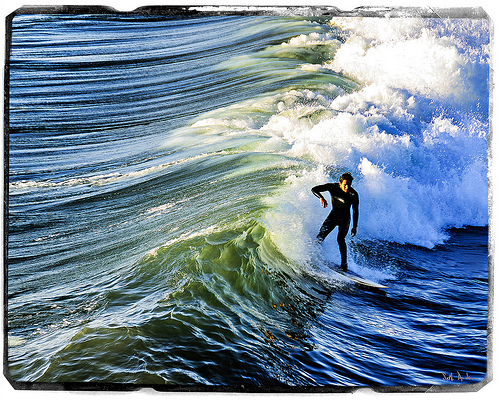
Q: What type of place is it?
A: It is an ocean.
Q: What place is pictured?
A: It is an ocean.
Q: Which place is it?
A: It is an ocean.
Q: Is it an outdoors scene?
A: Yes, it is outdoors.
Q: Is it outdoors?
A: Yes, it is outdoors.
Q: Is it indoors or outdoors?
A: It is outdoors.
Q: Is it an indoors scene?
A: No, it is outdoors.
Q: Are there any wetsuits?
A: Yes, there is a wetsuit.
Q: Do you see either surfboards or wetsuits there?
A: Yes, there is a wetsuit.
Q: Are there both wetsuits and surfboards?
A: Yes, there are both a wetsuit and a surfboard.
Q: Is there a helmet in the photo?
A: No, there are no helmets.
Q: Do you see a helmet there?
A: No, there are no helmets.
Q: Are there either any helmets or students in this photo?
A: No, there are no helmets or students.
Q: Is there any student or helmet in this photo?
A: No, there are no helmets or students.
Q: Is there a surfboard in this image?
A: Yes, there is a surfboard.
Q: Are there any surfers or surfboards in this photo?
A: Yes, there is a surfboard.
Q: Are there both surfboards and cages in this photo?
A: No, there is a surfboard but no cages.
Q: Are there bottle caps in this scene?
A: No, there are no bottle caps.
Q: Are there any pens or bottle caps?
A: No, there are no bottle caps or pens.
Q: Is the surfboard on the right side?
A: Yes, the surfboard is on the right of the image.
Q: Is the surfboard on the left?
A: No, the surfboard is on the right of the image.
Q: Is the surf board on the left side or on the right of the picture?
A: The surf board is on the right of the image.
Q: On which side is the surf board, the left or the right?
A: The surf board is on the right of the image.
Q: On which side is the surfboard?
A: The surfboard is on the right of the image.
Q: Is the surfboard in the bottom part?
A: Yes, the surfboard is in the bottom of the image.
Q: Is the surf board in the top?
A: No, the surf board is in the bottom of the image.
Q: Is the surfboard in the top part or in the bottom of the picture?
A: The surfboard is in the bottom of the image.